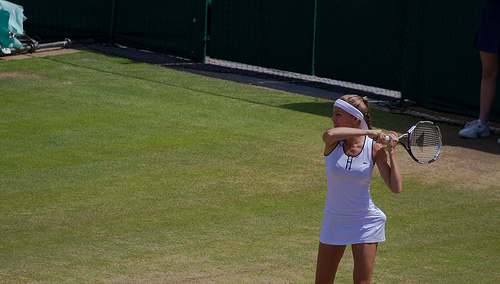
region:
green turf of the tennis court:
[17, 85, 244, 263]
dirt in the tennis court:
[449, 149, 497, 189]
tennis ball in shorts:
[373, 205, 398, 226]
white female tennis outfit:
[320, 152, 385, 243]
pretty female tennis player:
[311, 98, 390, 279]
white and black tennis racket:
[377, 115, 444, 161]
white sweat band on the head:
[330, 101, 367, 121]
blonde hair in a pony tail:
[358, 95, 373, 131]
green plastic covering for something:
[0, 7, 30, 49]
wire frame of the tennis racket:
[416, 130, 432, 151]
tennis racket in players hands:
[368, 116, 448, 167]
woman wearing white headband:
[328, 96, 368, 121]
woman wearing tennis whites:
[313, 123, 393, 250]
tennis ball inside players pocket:
[376, 204, 390, 227]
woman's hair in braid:
[354, 91, 378, 133]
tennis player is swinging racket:
[311, 86, 448, 282]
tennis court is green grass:
[2, 40, 498, 282]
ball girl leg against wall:
[448, 37, 498, 142]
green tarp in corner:
[0, 1, 33, 57]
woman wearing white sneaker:
[458, 115, 491, 146]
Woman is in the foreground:
[298, 86, 451, 282]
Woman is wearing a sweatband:
[318, 87, 393, 137]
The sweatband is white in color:
[306, 81, 389, 136]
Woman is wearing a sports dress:
[294, 116, 401, 266]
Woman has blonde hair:
[329, 88, 389, 144]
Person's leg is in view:
[446, 8, 499, 152]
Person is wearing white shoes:
[448, 106, 498, 152]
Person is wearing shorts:
[458, 6, 499, 63]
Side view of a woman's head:
[324, 86, 382, 151]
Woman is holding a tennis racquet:
[356, 103, 457, 175]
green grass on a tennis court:
[12, 98, 232, 185]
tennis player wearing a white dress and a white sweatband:
[321, 94, 388, 247]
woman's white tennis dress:
[324, 162, 381, 237]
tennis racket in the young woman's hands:
[378, 121, 439, 161]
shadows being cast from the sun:
[272, 98, 328, 121]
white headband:
[333, 99, 365, 121]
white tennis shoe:
[460, 120, 491, 139]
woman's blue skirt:
[474, 0, 497, 55]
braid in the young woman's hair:
[361, 95, 375, 127]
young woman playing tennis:
[329, 93, 376, 279]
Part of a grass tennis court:
[3, 56, 496, 279]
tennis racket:
[372, 117, 443, 165]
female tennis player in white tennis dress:
[311, 92, 403, 282]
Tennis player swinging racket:
[312, 91, 443, 282]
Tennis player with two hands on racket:
[311, 91, 443, 282]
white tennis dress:
[317, 132, 387, 246]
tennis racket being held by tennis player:
[368, 116, 443, 165]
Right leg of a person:
[457, 4, 495, 139]